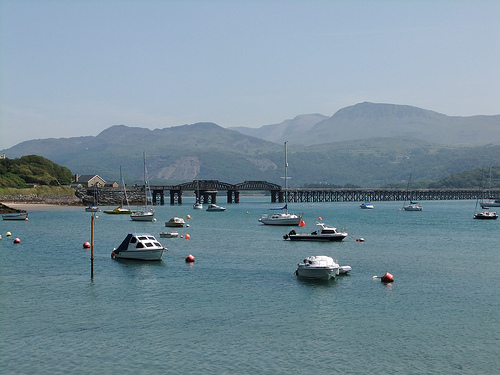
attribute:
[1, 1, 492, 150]
sky — hazy, cloudless, blue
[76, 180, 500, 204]
bridge — long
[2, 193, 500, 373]
water — clear, serene, calm, blue, still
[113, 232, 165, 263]
boat — vacant, front part, large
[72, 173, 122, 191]
part — house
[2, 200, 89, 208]
beach — flat, sandy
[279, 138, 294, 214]
sail — down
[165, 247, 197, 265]
buoy — boat anchor, line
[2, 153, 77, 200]
terrain — rugged, green, elevated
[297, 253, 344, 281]
boat — white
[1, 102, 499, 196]
mountains — Many , background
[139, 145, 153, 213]
sail — down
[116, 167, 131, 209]
sail — down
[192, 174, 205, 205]
sail — down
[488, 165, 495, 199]
sail — down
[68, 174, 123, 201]
property — waterfront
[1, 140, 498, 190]
forest — hilly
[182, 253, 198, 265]
bouy — red